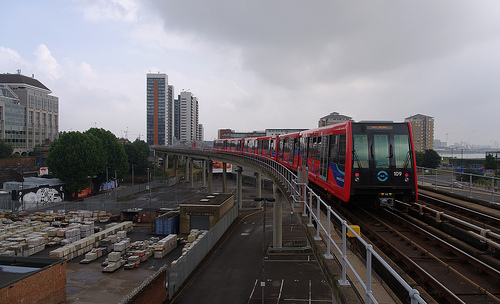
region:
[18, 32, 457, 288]
a passenger rail over a city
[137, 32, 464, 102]
the sky is cloudy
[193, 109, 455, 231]
the train is red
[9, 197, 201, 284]
lots of cars on the street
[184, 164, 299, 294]
a parking area on the ground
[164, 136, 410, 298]
a rail bridge over the area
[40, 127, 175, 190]
trees in the city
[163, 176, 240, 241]
a small brown building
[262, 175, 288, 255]
a pillar to hold the bridge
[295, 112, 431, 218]
the train is red,black and blue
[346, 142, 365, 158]
part of a window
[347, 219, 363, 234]
part of a rail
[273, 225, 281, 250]
part of a pillar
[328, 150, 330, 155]
edge of a train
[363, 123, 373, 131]
part of a train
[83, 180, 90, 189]
part of a branch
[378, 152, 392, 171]
part of a window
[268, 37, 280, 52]
part of the cloud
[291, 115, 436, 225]
Red train moving on tracks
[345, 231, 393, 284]
Metal railing next to train track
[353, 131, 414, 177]
Front windows of passenger train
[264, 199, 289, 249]
Concrete pole holding up train tracks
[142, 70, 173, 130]
Multi-story building beyond tracks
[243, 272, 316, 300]
Parking spaces on pavement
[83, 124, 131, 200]
Green trees in city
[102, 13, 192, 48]
Clouds in a blue sky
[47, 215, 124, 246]
Storage containers in a lot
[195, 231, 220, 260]
Metal fence near train tracks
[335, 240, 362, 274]
fence along the tracks.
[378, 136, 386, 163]
windshield on the train.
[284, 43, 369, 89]
clouds in the sky.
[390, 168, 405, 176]
number on the train.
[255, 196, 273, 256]
light pole beneath tracks.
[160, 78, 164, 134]
windows on tall building.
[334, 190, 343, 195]
red paint on train.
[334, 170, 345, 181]
blue paint on train.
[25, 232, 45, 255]
cargo in the lot.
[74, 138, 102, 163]
leaves on the tree.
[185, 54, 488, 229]
a train on a track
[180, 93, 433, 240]
a red train on a track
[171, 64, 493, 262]
a passenger train on a track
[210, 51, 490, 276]
a red passenger train on a track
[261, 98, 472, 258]
a train on a bridge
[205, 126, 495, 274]
a red train on a bridge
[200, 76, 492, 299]
a passenger train on a bridge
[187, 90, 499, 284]
a red passenger train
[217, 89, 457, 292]
a red passenger train moving on a track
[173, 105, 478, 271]
a train moving on a bridge